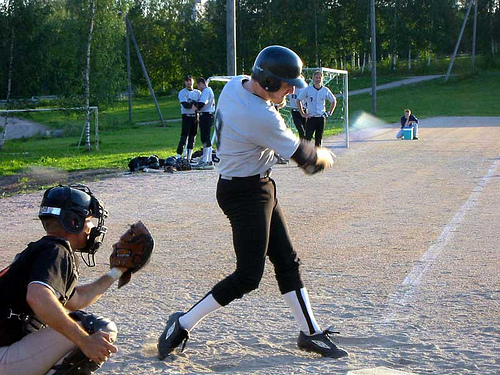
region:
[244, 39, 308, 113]
man wearing safety helmet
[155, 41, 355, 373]
man swinging baseball bat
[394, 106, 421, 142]
man squatting behind water cooler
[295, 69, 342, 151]
man watching baseball game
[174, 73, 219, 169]
two men talking to each other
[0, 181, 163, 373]
catcher posed to catch ball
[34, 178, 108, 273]
man wearing catcher's helmet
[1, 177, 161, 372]
man wearing catcher's mitt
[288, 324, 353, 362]
black baseball cleat in dirt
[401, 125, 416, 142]
teal green water pitcher on ground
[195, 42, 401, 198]
baseball player swinging bat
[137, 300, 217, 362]
toe pointed in a black shoe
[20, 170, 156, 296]
catcher with mitt extended out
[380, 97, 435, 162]
person crouched behind a blue bucket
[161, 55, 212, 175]
players in black and white facing each other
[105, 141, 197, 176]
sports-gear bags left on the ground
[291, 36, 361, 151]
man watching game with hands on hips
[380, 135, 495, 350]
faint white line drawn on tan ground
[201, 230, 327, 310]
one knee bent and the other straight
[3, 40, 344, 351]
catcher crouched behind hitter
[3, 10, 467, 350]
a baseball team in play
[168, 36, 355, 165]
a few baseball players in uniform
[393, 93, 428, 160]
a man with a cooler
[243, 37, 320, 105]
a hard black helmet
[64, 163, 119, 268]
a catchers face guard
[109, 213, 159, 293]
a leather baseball glove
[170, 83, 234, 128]
a pair of grey jerseys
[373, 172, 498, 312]
a white line chalked into the ground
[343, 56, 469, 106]
a trail in the grass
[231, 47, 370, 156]
a net goal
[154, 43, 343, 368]
a baseball player standing at home plate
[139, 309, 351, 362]
a baseball player's shoes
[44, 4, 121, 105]
a lush green tree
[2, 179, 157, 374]
a catcher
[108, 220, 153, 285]
a catcher's mitt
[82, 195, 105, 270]
a catcher's mask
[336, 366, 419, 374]
home plate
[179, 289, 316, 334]
a ball player's socks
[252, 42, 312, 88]
a baseball player's batting helmet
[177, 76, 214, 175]
two baseball players standing together talking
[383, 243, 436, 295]
part of a white line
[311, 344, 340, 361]
part of a boot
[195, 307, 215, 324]
part of a sock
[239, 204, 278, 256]
part of a trouser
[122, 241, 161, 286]
part of a glove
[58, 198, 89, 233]
part of a helmet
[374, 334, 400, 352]
part of some sand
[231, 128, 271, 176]
part of a white top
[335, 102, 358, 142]
part of a post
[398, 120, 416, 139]
part of a container